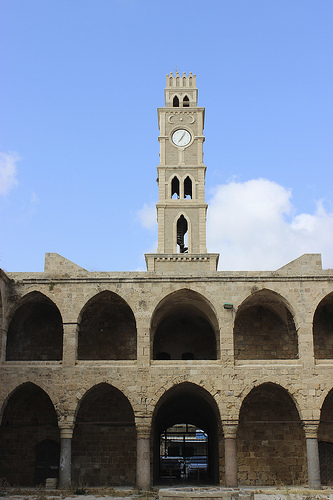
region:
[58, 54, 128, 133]
A very vivid blue sky.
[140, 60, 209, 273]
Tall clock tower in the sky.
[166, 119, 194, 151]
A white clock on the tower.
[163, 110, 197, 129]
Two crescent moons above the clock.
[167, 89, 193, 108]
Two arches above the moons.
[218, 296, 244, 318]
Green light on the brick wall.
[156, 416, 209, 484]
Metal gate beyond the arch.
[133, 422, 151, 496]
Stone pillars between the arches.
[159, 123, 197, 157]
this is a clock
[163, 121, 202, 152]
clock face is white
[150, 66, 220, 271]
clock on top of tower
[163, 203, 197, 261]
single archway in town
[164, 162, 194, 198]
double archway in tower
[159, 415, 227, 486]
gate on other side of archway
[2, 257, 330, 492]
building is tan rocks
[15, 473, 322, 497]
dry grass on ground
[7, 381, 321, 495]
The arches in the building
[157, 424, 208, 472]
The gate is made of metal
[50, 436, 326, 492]
The pillars in the building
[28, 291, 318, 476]
The building is the color beige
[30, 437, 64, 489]
The door into the building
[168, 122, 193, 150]
The clock on top of the building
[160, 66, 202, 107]
The top of the building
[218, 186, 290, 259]
The clouds are white and fluffy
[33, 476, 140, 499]
The ground is made of concrete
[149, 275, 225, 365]
This is an entrance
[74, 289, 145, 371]
This is an entrance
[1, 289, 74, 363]
This is an entrance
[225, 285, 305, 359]
This is an entrance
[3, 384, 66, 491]
This is an entrance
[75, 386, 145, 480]
This is an entrance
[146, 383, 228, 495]
This is an entrance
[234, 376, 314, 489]
This is an entrance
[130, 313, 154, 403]
bricks on a building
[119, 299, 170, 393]
bricks on a building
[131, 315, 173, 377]
bricks on a building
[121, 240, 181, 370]
bricks on a building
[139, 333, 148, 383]
bricks on a building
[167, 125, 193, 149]
white clock built into tower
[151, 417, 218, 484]
iron gates securing entry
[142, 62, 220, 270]
old tower with white clock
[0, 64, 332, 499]
old building with large columns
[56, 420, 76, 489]
one of many large columns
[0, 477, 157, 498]
patch of green and dried grass